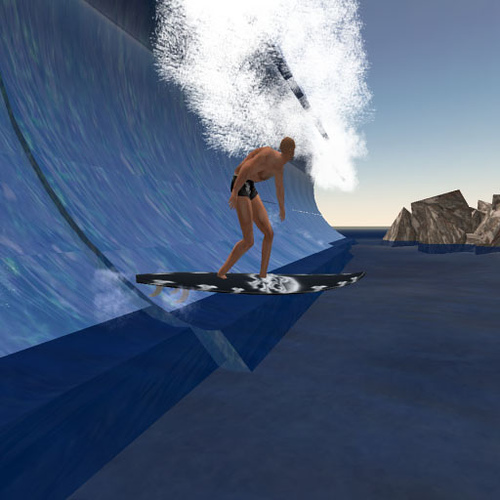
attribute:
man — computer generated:
[213, 136, 300, 285]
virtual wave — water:
[74, 20, 458, 192]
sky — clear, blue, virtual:
[308, 4, 498, 231]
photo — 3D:
[6, 5, 498, 498]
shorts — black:
[232, 173, 258, 195]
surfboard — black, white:
[126, 258, 372, 302]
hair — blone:
[266, 121, 304, 153]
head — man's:
[273, 135, 298, 157]